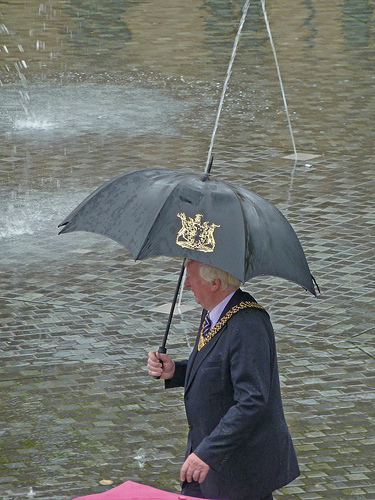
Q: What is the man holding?
A: An umbrella.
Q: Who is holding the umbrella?
A: A man.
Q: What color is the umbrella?
A: Black.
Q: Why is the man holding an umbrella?
A: It is raining.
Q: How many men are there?
A: One.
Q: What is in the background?
A: A fountain.